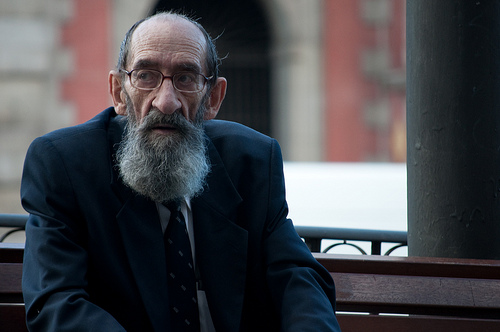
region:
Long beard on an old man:
[111, 135, 218, 204]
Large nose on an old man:
[152, 75, 182, 115]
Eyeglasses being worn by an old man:
[109, 53, 226, 94]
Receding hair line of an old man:
[121, 13, 221, 64]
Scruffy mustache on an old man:
[127, 105, 202, 135]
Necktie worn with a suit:
[155, 188, 209, 330]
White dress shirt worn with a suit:
[141, 181, 227, 330]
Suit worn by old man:
[19, 93, 338, 330]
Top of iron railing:
[292, 225, 415, 257]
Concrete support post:
[404, 0, 498, 262]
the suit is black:
[210, 231, 230, 251]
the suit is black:
[251, 249, 263, 276]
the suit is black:
[225, 234, 236, 251]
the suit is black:
[236, 254, 244, 276]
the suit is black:
[233, 255, 244, 285]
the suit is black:
[207, 245, 223, 264]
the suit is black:
[227, 263, 242, 289]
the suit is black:
[227, 152, 240, 179]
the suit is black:
[234, 303, 252, 320]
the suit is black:
[220, 296, 240, 319]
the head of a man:
[106, 8, 235, 162]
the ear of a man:
[201, 72, 233, 121]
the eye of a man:
[134, 68, 163, 87]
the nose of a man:
[149, 70, 184, 116]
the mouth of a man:
[144, 120, 184, 137]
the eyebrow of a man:
[130, 53, 162, 73]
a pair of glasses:
[110, 60, 220, 97]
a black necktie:
[155, 189, 207, 330]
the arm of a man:
[12, 140, 132, 330]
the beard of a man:
[114, 83, 211, 208]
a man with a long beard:
[96, 5, 241, 200]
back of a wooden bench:
[1, 238, 489, 322]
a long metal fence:
[2, 208, 434, 263]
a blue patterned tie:
[139, 197, 219, 330]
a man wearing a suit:
[13, 6, 355, 326]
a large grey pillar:
[398, 11, 497, 280]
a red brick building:
[23, 3, 430, 180]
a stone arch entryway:
[123, 0, 336, 183]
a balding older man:
[85, 4, 246, 201]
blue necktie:
[154, 247, 226, 318]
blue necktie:
[113, 221, 226, 291]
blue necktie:
[147, 226, 254, 301]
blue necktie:
[100, 191, 245, 306]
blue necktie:
[134, 242, 231, 279]